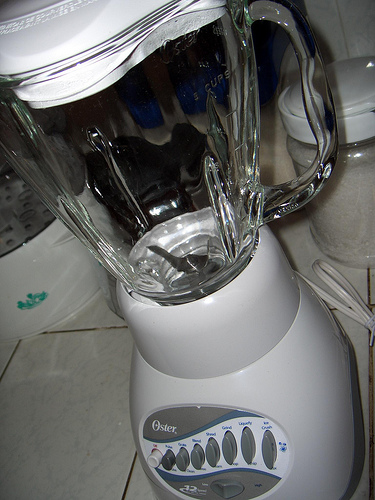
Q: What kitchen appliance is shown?
A: Blender.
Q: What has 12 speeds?
A: Blender.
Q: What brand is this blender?
A: Oster.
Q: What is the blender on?
A: Countertop.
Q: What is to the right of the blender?
A: Storage jar.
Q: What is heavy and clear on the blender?
A: Jar.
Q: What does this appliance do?
A: Blend.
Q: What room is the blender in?
A: Kitchen.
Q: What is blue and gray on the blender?
A: Label.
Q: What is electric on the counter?
A: Blender.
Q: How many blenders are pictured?
A: 1.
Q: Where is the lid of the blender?
A: On top of the blender.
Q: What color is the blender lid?
A: White.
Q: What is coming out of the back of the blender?
A: Plug.